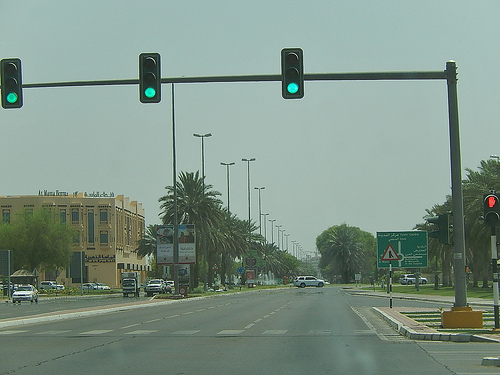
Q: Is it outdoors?
A: Yes, it is outdoors.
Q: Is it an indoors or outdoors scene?
A: It is outdoors.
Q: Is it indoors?
A: No, it is outdoors.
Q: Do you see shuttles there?
A: No, there are no shuttles.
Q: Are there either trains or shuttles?
A: No, there are no shuttles or trains.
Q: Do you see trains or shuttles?
A: No, there are no shuttles or trains.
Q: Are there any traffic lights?
A: Yes, there is a traffic light.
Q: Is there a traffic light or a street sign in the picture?
A: Yes, there is a traffic light.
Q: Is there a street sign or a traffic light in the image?
A: Yes, there is a traffic light.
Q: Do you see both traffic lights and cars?
A: Yes, there are both a traffic light and a car.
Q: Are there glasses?
A: No, there are no glasses.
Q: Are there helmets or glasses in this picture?
A: No, there are no glasses or helmets.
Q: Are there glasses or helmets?
A: No, there are no glasses or helmets.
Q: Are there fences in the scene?
A: No, there are no fences.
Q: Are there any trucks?
A: Yes, there is a truck.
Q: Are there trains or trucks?
A: Yes, there is a truck.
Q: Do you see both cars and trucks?
A: Yes, there are both a truck and a car.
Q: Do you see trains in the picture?
A: No, there are no trains.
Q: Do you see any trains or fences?
A: No, there are no trains or fences.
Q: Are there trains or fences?
A: No, there are no trains or fences.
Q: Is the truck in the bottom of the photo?
A: Yes, the truck is in the bottom of the image.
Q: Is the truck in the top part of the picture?
A: No, the truck is in the bottom of the image.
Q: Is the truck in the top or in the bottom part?
A: The truck is in the bottom of the image.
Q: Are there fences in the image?
A: No, there are no fences.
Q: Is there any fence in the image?
A: No, there are no fences.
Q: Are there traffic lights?
A: Yes, there is a traffic light.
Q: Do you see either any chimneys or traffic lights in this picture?
A: Yes, there is a traffic light.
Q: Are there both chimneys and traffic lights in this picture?
A: No, there is a traffic light but no chimneys.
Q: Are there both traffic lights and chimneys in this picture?
A: No, there is a traffic light but no chimneys.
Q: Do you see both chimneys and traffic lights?
A: No, there is a traffic light but no chimneys.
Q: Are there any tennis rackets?
A: No, there are no tennis rackets.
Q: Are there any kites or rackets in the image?
A: No, there are no rackets or kites.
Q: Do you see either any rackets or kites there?
A: No, there are no rackets or kites.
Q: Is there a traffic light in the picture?
A: Yes, there is a traffic light.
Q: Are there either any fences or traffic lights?
A: Yes, there is a traffic light.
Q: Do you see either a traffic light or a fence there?
A: Yes, there is a traffic light.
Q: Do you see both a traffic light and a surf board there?
A: No, there is a traffic light but no surfboards.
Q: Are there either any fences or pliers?
A: No, there are no fences or pliers.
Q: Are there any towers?
A: No, there are no towers.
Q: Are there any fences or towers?
A: No, there are no towers or fences.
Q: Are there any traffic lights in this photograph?
A: Yes, there is a traffic light.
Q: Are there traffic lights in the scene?
A: Yes, there is a traffic light.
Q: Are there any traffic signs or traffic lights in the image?
A: Yes, there is a traffic light.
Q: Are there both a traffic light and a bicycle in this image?
A: No, there is a traffic light but no bicycles.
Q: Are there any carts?
A: No, there are no carts.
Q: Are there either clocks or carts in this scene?
A: No, there are no carts or clocks.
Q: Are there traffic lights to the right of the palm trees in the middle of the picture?
A: Yes, there is a traffic light to the right of the palm trees.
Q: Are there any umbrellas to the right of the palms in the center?
A: No, there is a traffic light to the right of the palms.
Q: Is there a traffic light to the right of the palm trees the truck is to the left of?
A: Yes, there is a traffic light to the right of the palm trees.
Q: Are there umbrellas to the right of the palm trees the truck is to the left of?
A: No, there is a traffic light to the right of the palms.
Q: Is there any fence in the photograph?
A: No, there are no fences.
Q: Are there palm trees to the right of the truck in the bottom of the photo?
A: Yes, there are palm trees to the right of the truck.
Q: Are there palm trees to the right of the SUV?
A: Yes, there are palm trees to the right of the SUV.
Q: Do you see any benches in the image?
A: No, there are no benches.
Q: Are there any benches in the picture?
A: No, there are no benches.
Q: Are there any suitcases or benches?
A: No, there are no benches or suitcases.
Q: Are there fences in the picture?
A: No, there are no fences.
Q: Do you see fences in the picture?
A: No, there are no fences.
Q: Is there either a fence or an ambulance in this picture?
A: No, there are no fences or ambulances.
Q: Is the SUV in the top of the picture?
A: No, the SUV is in the bottom of the image.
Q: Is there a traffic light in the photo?
A: Yes, there is a traffic light.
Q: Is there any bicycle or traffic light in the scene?
A: Yes, there is a traffic light.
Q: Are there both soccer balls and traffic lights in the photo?
A: No, there is a traffic light but no soccer balls.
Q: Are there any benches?
A: No, there are no benches.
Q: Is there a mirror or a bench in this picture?
A: No, there are no benches or mirrors.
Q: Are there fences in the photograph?
A: No, there are no fences.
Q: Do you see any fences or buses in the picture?
A: No, there are no fences or buses.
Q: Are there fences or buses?
A: No, there are no fences or buses.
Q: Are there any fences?
A: No, there are no fences.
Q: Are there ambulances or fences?
A: No, there are no fences or ambulances.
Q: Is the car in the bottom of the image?
A: Yes, the car is in the bottom of the image.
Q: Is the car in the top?
A: No, the car is in the bottom of the image.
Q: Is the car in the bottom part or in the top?
A: The car is in the bottom of the image.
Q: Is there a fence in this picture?
A: No, there are no fences.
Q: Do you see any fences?
A: No, there are no fences.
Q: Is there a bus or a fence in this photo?
A: No, there are no fences or buses.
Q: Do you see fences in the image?
A: No, there are no fences.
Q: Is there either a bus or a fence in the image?
A: No, there are no fences or buses.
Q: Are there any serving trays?
A: No, there are no serving trays.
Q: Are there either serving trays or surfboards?
A: No, there are no serving trays or surfboards.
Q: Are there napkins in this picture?
A: No, there are no napkins.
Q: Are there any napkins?
A: No, there are no napkins.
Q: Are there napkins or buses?
A: No, there are no napkins or buses.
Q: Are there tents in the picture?
A: No, there are no tents.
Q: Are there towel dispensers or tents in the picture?
A: No, there are no tents or towel dispensers.